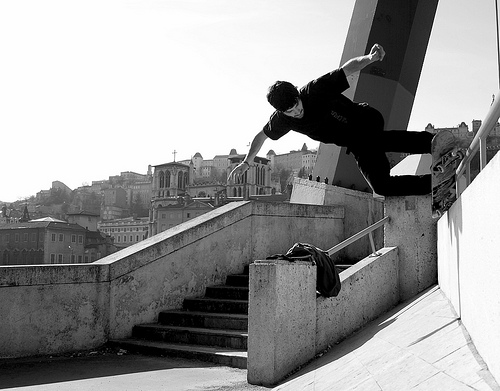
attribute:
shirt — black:
[250, 69, 358, 154]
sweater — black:
[270, 221, 343, 309]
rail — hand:
[309, 210, 389, 266]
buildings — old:
[16, 126, 291, 251]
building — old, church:
[143, 145, 246, 227]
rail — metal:
[318, 212, 388, 255]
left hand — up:
[363, 40, 389, 69]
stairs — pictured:
[113, 227, 371, 370]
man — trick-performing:
[227, 36, 433, 226]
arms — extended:
[224, 35, 382, 185]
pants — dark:
[345, 99, 431, 207]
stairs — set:
[171, 298, 227, 343]